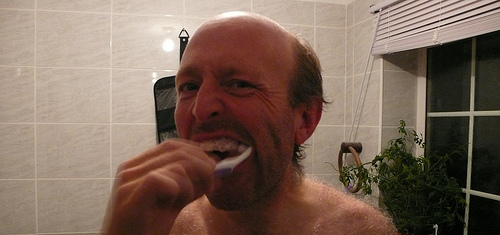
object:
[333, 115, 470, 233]
plant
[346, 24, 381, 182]
rope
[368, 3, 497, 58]
mini-blinds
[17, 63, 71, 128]
grout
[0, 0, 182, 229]
tile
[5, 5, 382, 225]
wall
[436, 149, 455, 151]
ground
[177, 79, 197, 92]
eye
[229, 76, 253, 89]
eye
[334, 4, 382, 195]
corner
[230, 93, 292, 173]
cheek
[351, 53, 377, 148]
rod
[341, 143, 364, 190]
towel rack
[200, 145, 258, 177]
toothbrush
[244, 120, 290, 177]
cheel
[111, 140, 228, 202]
finger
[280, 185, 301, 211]
part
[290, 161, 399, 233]
shoulder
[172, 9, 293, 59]
bald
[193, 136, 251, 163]
teeth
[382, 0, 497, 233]
window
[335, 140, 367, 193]
towel ring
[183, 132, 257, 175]
mouth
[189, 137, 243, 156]
toothpaste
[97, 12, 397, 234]
middle aged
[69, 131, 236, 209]
hand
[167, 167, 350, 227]
neck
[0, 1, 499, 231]
bathroom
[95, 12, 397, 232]
man